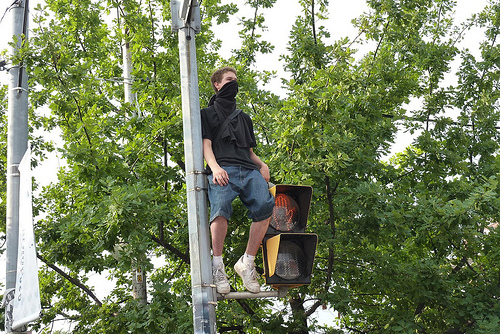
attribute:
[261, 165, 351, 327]
light — crosswalk, red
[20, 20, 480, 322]
tree — green 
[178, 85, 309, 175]
shirt — black 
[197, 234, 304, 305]
socks — white 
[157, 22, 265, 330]
pole — large 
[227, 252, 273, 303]
sneakers — white 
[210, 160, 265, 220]
shorts — blue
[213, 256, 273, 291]
shoes — white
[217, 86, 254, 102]
mask — black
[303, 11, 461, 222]
section — large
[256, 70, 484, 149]
power line — black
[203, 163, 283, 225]
shorts — denim, blue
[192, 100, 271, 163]
shirt — black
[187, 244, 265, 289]
tennis shoes — white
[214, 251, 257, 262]
socks — white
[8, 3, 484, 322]
trees — green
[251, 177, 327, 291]
red light — pedestrian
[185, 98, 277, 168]
shirt — black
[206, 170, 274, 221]
shorts — jean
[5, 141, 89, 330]
advertisement — hanging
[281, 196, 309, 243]
lights — held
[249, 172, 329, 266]
holder — yellow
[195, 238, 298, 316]
shoes — white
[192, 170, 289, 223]
jeans — blue, shorts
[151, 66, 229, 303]
poll — tall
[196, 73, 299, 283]
man — standing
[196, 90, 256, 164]
shirt — black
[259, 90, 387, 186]
tree — green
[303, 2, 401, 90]
sky — white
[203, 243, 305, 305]
shoes — white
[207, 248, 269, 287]
sock — white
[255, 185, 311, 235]
hand — orange, glowing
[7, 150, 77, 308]
flag — white